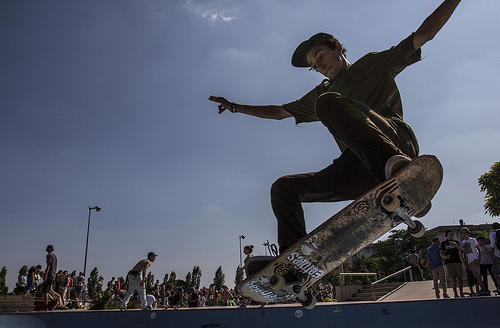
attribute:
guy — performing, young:
[208, 2, 472, 273]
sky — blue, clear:
[1, 5, 497, 285]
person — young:
[459, 226, 490, 297]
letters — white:
[287, 252, 325, 281]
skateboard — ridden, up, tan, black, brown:
[237, 152, 443, 312]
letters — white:
[248, 280, 282, 303]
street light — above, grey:
[83, 205, 103, 286]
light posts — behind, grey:
[238, 233, 246, 274]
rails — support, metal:
[370, 264, 414, 306]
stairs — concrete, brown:
[348, 279, 405, 303]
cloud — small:
[191, 4, 242, 26]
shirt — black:
[282, 32, 423, 152]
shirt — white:
[459, 237, 481, 264]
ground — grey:
[2, 301, 499, 326]